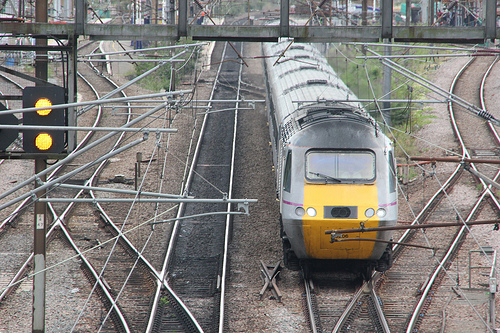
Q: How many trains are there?
A: One.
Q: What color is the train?
A: Yellow and silver.